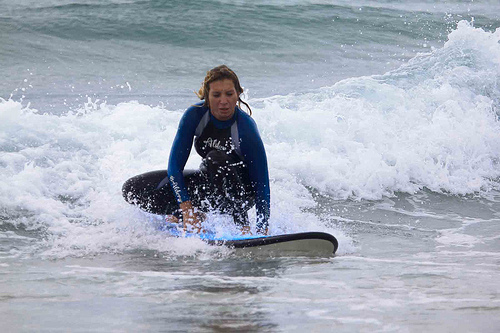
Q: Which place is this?
A: It is an ocean.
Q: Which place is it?
A: It is an ocean.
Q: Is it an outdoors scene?
A: Yes, it is outdoors.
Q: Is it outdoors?
A: Yes, it is outdoors.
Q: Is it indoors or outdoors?
A: It is outdoors.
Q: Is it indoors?
A: No, it is outdoors.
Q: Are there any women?
A: Yes, there is a woman.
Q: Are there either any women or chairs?
A: Yes, there is a woman.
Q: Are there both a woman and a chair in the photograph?
A: No, there is a woman but no chairs.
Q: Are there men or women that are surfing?
A: Yes, the woman is surfing.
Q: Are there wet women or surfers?
A: Yes, there is a wet woman.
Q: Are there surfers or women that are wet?
A: Yes, the woman is wet.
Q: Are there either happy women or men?
A: Yes, there is a happy woman.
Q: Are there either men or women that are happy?
A: Yes, the woman is happy.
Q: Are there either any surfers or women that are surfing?
A: Yes, the woman is surfing.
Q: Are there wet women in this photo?
A: Yes, there is a wet woman.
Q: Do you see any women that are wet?
A: Yes, there is a woman that is wet.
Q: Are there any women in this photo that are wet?
A: Yes, there is a woman that is wet.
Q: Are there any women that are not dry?
A: Yes, there is a wet woman.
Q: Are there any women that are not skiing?
A: Yes, there is a woman that is surfing.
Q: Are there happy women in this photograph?
A: Yes, there is a happy woman.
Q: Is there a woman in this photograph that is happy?
A: Yes, there is a woman that is happy.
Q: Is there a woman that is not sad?
A: Yes, there is a happy woman.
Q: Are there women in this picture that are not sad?
A: Yes, there is a happy woman.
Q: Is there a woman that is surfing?
A: Yes, there is a woman that is surfing.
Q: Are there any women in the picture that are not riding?
A: Yes, there is a woman that is surfing.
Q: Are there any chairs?
A: No, there are no chairs.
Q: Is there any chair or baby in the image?
A: No, there are no chairs or babies.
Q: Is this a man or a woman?
A: This is a woman.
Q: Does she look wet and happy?
A: Yes, the woman is wet and happy.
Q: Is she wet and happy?
A: Yes, the woman is wet and happy.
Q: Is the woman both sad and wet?
A: No, the woman is wet but happy.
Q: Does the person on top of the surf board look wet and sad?
A: No, the woman is wet but happy.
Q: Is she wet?
A: Yes, the woman is wet.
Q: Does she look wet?
A: Yes, the woman is wet.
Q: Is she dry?
A: No, the woman is wet.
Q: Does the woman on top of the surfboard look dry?
A: No, the woman is wet.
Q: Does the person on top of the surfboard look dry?
A: No, the woman is wet.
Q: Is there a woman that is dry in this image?
A: No, there is a woman but she is wet.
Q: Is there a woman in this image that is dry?
A: No, there is a woman but she is wet.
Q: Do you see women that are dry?
A: No, there is a woman but she is wet.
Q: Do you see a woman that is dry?
A: No, there is a woman but she is wet.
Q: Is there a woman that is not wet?
A: No, there is a woman but she is wet.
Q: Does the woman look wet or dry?
A: The woman is wet.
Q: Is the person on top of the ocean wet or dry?
A: The woman is wet.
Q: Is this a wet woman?
A: Yes, this is a wet woman.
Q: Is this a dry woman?
A: No, this is a wet woman.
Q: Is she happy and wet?
A: Yes, the woman is happy and wet.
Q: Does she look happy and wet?
A: Yes, the woman is happy and wet.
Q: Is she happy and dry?
A: No, the woman is happy but wet.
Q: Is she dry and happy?
A: No, the woman is happy but wet.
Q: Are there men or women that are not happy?
A: No, there is a woman but she is happy.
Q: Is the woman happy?
A: Yes, the woman is happy.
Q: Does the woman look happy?
A: Yes, the woman is happy.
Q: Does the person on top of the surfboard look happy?
A: Yes, the woman is happy.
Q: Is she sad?
A: No, the woman is happy.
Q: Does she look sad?
A: No, the woman is happy.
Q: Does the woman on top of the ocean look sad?
A: No, the woman is happy.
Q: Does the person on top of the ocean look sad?
A: No, the woman is happy.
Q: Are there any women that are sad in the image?
A: No, there is a woman but she is happy.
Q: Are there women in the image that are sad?
A: No, there is a woman but she is happy.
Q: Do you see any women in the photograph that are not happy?
A: No, there is a woman but she is happy.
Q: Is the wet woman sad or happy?
A: The woman is happy.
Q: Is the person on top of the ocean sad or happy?
A: The woman is happy.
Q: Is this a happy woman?
A: Yes, this is a happy woman.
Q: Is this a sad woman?
A: No, this is a happy woman.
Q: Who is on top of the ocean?
A: The woman is on top of the ocean.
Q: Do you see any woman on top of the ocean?
A: Yes, there is a woman on top of the ocean.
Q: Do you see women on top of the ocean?
A: Yes, there is a woman on top of the ocean.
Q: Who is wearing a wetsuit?
A: The woman is wearing a wetsuit.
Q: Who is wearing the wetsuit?
A: The woman is wearing a wetsuit.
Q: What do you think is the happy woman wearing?
A: The woman is wearing a wetsuit.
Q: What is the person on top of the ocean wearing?
A: The woman is wearing a wetsuit.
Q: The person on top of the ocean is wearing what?
A: The woman is wearing a wetsuit.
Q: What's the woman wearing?
A: The woman is wearing a wetsuit.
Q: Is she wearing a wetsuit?
A: Yes, the woman is wearing a wetsuit.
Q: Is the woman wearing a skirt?
A: No, the woman is wearing a wetsuit.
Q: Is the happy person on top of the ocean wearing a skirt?
A: No, the woman is wearing a wetsuit.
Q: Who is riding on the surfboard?
A: The woman is riding on the surfboard.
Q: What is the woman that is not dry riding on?
A: The woman is riding on the surfboard.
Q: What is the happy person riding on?
A: The woman is riding on the surfboard.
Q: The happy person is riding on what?
A: The woman is riding on the surfboard.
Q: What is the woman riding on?
A: The woman is riding on the surfboard.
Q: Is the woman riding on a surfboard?
A: Yes, the woman is riding on a surfboard.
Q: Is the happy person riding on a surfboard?
A: Yes, the woman is riding on a surfboard.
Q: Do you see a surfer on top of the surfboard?
A: No, there is a woman on top of the surfboard.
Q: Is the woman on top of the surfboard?
A: Yes, the woman is on top of the surfboard.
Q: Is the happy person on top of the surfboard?
A: Yes, the woman is on top of the surfboard.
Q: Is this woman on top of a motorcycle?
A: No, the woman is on top of the surfboard.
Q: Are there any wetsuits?
A: Yes, there is a wetsuit.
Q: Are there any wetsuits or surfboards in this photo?
A: Yes, there is a wetsuit.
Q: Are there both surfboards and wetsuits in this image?
A: Yes, there are both a wetsuit and a surfboard.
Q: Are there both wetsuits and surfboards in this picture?
A: Yes, there are both a wetsuit and a surfboard.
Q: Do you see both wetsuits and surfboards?
A: Yes, there are both a wetsuit and a surfboard.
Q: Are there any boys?
A: No, there are no boys.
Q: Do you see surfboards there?
A: Yes, there is a surfboard.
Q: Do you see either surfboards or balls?
A: Yes, there is a surfboard.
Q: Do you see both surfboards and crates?
A: No, there is a surfboard but no crates.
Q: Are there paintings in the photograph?
A: No, there are no paintings.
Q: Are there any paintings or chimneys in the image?
A: No, there are no paintings or chimneys.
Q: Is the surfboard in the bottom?
A: Yes, the surfboard is in the bottom of the image.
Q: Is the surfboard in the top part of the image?
A: No, the surfboard is in the bottom of the image.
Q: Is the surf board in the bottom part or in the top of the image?
A: The surf board is in the bottom of the image.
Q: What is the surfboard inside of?
A: The surfboard is inside the ocean.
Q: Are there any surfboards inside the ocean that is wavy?
A: Yes, there is a surfboard inside the ocean.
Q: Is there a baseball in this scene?
A: No, there are no baseballs.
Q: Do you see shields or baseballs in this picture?
A: No, there are no baseballs or shields.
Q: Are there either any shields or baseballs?
A: No, there are no baseballs or shields.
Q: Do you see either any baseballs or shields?
A: No, there are no baseballs or shields.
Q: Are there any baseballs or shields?
A: No, there are no baseballs or shields.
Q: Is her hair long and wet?
A: Yes, the hair is long and wet.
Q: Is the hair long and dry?
A: No, the hair is long but wet.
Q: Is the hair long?
A: Yes, the hair is long.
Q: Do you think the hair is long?
A: Yes, the hair is long.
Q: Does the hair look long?
A: Yes, the hair is long.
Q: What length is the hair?
A: The hair is long.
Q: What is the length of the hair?
A: The hair is long.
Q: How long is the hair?
A: The hair is long.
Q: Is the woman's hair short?
A: No, the hair is long.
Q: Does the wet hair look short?
A: No, the hair is long.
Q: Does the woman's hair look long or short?
A: The hair is long.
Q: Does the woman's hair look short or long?
A: The hair is long.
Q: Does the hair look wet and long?
A: Yes, the hair is wet and long.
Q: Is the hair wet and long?
A: Yes, the hair is wet and long.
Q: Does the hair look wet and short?
A: No, the hair is wet but long.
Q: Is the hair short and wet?
A: No, the hair is wet but long.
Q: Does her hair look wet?
A: Yes, the hair is wet.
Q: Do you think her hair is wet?
A: Yes, the hair is wet.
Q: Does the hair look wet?
A: Yes, the hair is wet.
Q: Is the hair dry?
A: No, the hair is wet.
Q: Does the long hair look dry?
A: No, the hair is wet.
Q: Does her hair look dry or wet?
A: The hair is wet.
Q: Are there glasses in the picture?
A: No, there are no glasses.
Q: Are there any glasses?
A: No, there are no glasses.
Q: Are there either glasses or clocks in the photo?
A: No, there are no glasses or clocks.